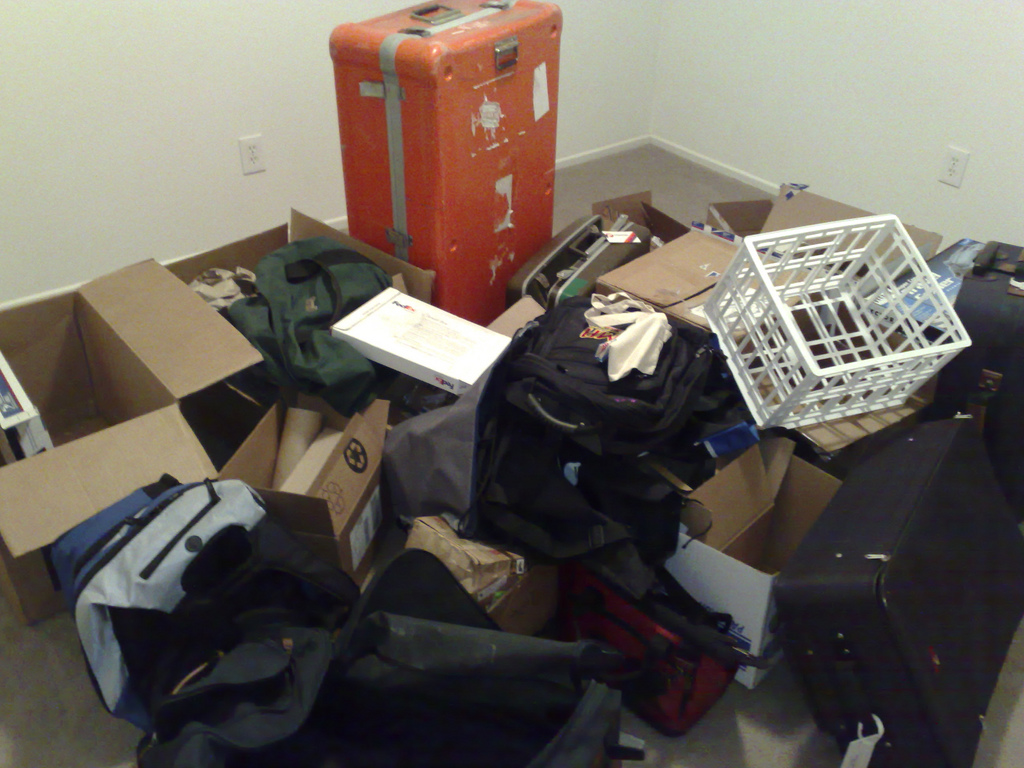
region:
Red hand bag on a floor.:
[552, 540, 748, 750]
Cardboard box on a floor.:
[211, 402, 399, 561]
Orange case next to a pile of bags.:
[321, 0, 563, 343]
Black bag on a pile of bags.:
[495, 307, 745, 464]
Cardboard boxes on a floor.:
[8, 240, 429, 509]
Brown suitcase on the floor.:
[496, 192, 645, 338]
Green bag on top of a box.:
[239, 247, 435, 440]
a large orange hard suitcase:
[322, 1, 572, 335]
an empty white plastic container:
[682, 208, 976, 434]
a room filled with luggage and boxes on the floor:
[2, 1, 1020, 766]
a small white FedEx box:
[329, 282, 516, 399]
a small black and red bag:
[541, 538, 745, 741]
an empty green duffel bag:
[221, 224, 399, 403]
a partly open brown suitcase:
[499, 209, 658, 318]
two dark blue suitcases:
[773, 235, 1023, 764]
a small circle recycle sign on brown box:
[342, 433, 371, 473]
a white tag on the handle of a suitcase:
[830, 708, 885, 766]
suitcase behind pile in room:
[320, 6, 592, 340]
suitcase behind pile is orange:
[316, 5, 592, 339]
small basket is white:
[696, 210, 984, 448]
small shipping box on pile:
[320, 268, 514, 414]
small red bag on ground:
[553, 536, 754, 752]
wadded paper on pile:
[575, 277, 681, 395]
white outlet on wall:
[226, 129, 271, 187]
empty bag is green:
[218, 236, 416, 429]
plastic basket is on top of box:
[700, 210, 973, 432]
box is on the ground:
[0, 251, 268, 622]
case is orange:
[332, 0, 564, 329]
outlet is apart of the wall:
[232, 127, 271, 173]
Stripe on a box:
[366, 82, 423, 244]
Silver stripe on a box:
[369, 66, 423, 243]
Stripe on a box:
[376, 111, 418, 223]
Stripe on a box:
[369, 82, 409, 128]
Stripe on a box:
[381, 162, 424, 230]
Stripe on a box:
[375, 83, 415, 157]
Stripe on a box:
[384, 195, 417, 263]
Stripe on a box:
[373, 86, 411, 159]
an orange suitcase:
[312, 0, 579, 321]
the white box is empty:
[690, 194, 984, 449]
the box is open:
[4, 231, 271, 580]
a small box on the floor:
[222, 395, 413, 595]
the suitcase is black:
[757, 391, 1022, 765]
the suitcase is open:
[501, 186, 662, 330]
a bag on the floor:
[54, 465, 303, 726]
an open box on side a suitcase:
[669, 414, 856, 677]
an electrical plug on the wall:
[226, 122, 278, 190]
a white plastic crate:
[709, 207, 916, 463]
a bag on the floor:
[138, 644, 396, 750]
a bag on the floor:
[787, 501, 939, 720]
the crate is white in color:
[711, 212, 971, 435]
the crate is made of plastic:
[710, 206, 973, 431]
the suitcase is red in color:
[332, 1, 566, 312]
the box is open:
[3, 260, 263, 611]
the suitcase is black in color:
[771, 404, 1022, 753]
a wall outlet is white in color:
[236, 132, 266, 177]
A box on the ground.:
[631, 424, 854, 728]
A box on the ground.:
[367, 510, 609, 703]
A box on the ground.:
[252, 400, 417, 598]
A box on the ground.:
[6, 193, 316, 604]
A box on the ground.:
[558, 209, 793, 355]